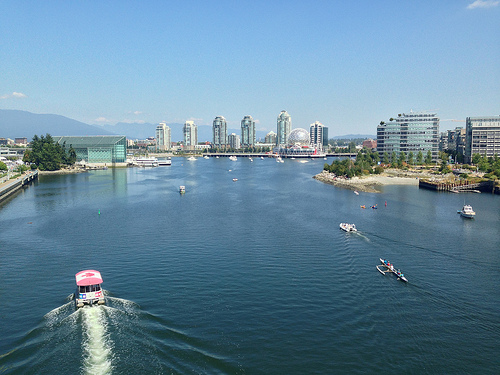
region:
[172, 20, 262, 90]
sky above the buildings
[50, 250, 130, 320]
boat in the water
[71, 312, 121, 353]
white water behind boat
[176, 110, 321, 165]
buildings in the background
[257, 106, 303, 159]
tall building in the distance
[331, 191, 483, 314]
three boats in the water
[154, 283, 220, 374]
ripples in the water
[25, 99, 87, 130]
mountain in the distance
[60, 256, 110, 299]
top of the boat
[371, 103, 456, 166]
buildig with many windows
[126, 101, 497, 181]
buildings along the shore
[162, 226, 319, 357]
body of water with boats in it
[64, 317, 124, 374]
stream of water from boat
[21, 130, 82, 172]
set of trees on shore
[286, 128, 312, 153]
globular building on shore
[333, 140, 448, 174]
island of trees on land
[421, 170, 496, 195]
protruding deck into water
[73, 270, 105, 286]
symbol on top of boat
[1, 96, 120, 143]
mountains in the far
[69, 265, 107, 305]
The boat with the pink canopy.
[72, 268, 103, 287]
The pink canopy on the boat.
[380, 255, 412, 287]
The long row boat.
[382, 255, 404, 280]
The people sitting in the long row boat.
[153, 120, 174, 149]
The short tan building located on the left in the middle line up of buildings.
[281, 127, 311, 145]
The round structure in the middle near the buildings.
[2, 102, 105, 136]
The mountain on the left.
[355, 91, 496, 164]
The buildings on the right.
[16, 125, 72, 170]
The trees on the left.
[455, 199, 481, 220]
The boat on the right.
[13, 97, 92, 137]
mountain in the background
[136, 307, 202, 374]
ripples in the water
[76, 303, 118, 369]
white water behind the boat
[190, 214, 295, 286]
water under the boats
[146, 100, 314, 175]
buildings in the distance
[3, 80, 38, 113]
white cloud in the sky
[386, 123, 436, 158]
windows on the building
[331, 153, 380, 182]
trees next to the water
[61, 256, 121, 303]
boat with red top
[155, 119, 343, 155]
buildings along water shore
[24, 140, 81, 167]
trees beside the water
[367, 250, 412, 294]
people rowing in a kayak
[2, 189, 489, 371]
body of water in a city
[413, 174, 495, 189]
boating dock near water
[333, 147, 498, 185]
shrubbery beside the water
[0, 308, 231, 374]
water ripples from the boat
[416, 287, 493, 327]
water ripples from kayak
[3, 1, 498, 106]
blue clear sky with no clouds